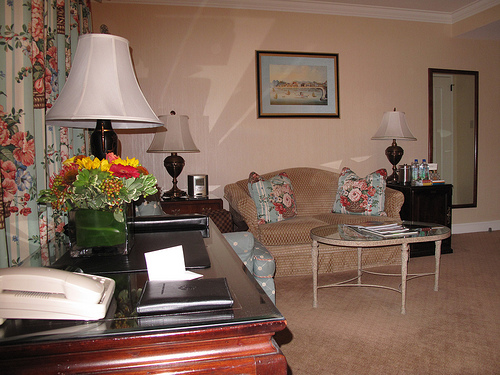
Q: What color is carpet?
A: Tan.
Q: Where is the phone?
A: On desk.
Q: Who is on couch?
A: No one.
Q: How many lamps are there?
A: Three.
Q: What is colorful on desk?
A: Flowers.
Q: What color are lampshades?
A: White.